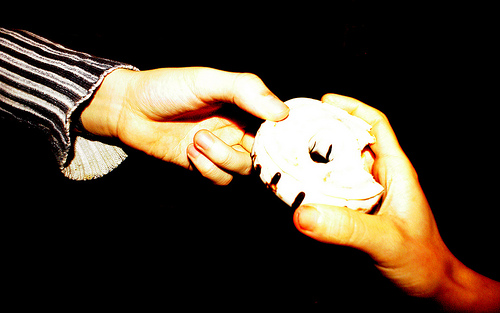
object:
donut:
[250, 96, 384, 215]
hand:
[103, 56, 283, 182]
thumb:
[202, 64, 294, 114]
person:
[5, 9, 310, 181]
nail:
[257, 91, 289, 120]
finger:
[181, 66, 294, 185]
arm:
[0, 27, 128, 183]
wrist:
[76, 57, 148, 151]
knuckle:
[351, 78, 425, 249]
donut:
[250, 93, 388, 213]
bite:
[342, 112, 389, 209]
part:
[332, 118, 395, 191]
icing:
[299, 120, 354, 190]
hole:
[302, 133, 346, 172]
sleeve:
[45, 45, 145, 182]